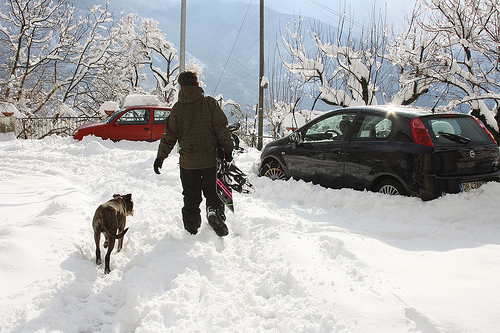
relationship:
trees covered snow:
[297, 25, 483, 102] [348, 58, 400, 117]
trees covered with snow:
[297, 25, 483, 102] [348, 58, 400, 117]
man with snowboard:
[161, 69, 217, 121] [213, 135, 262, 228]